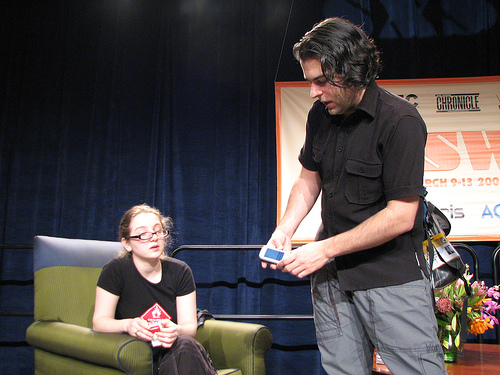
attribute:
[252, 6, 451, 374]
man — young, demonstrating 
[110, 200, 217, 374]
person — young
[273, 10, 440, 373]
person — young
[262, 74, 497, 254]
sign — white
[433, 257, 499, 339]
flowers — orange, pink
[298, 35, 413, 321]
man — young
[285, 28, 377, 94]
face — young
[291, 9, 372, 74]
black hair — wavy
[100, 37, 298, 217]
curtain — dark blue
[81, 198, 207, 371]
lady — red haired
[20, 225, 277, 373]
chair — green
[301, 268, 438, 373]
pants — gray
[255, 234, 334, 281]
hand — man's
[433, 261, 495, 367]
vase — full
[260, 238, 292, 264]
phone — cell phone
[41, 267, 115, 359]
sofa — green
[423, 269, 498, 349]
flowers — mixed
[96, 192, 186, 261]
blonde hair — dirty 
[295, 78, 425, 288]
shirt — black, collared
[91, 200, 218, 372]
girl — sitting down